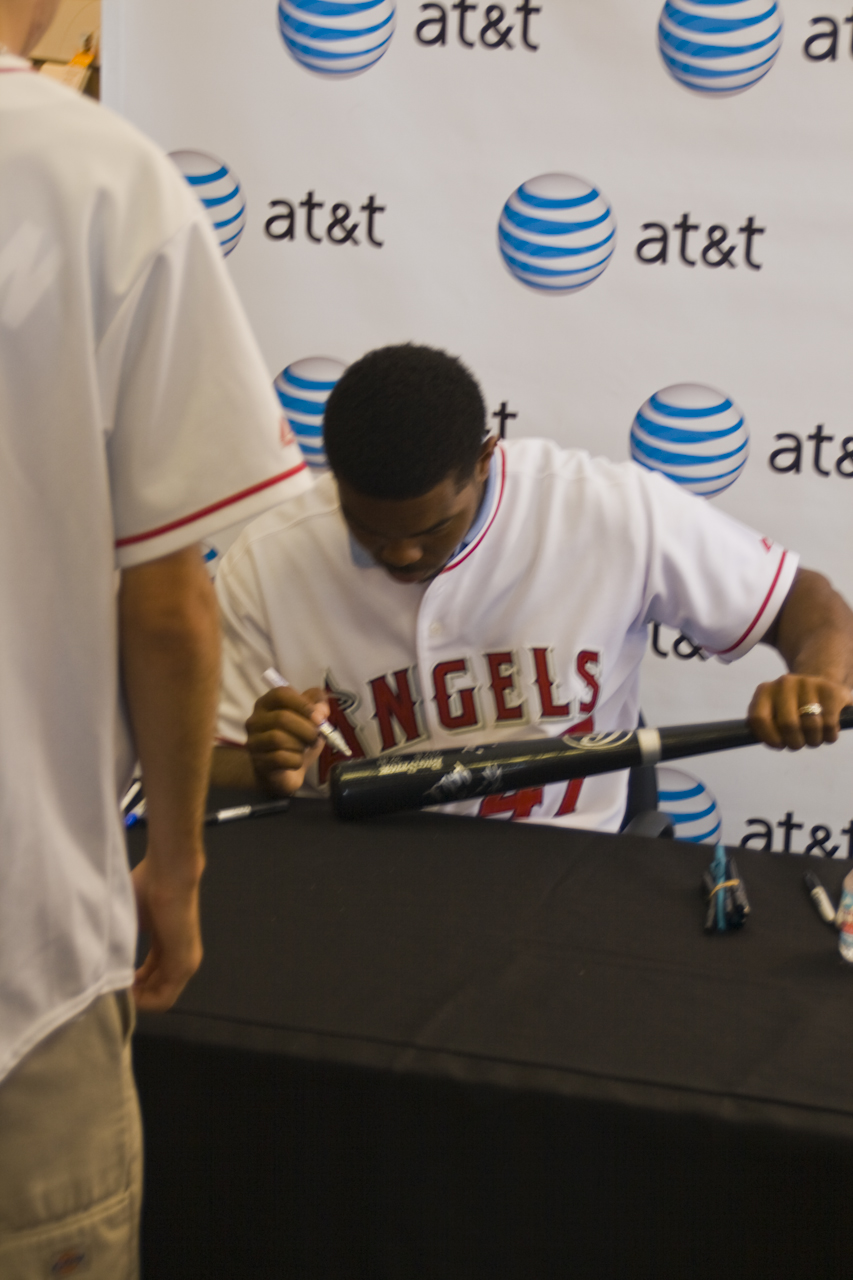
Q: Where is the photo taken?
A: At a signing.